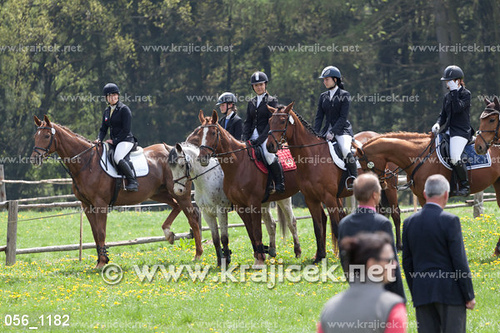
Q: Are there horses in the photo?
A: Yes, there is a horse.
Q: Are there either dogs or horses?
A: Yes, there is a horse.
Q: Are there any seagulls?
A: No, there are no seagulls.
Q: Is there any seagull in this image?
A: No, there are no seagulls.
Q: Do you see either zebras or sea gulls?
A: No, there are no sea gulls or zebras.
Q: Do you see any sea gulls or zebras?
A: No, there are no sea gulls or zebras.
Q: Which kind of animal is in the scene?
A: The animal is a horse.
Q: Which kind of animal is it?
A: The animal is a horse.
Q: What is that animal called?
A: This is a horse.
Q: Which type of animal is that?
A: This is a horse.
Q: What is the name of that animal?
A: This is a horse.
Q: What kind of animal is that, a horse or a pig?
A: This is a horse.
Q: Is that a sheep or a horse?
A: That is a horse.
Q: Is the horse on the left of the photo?
A: Yes, the horse is on the left of the image.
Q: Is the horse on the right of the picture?
A: No, the horse is on the left of the image.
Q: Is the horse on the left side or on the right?
A: The horse is on the left of the image.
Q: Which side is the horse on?
A: The horse is on the left of the image.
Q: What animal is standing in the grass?
A: The animal is a horse.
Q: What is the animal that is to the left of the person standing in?
A: The horse is standing in the grass.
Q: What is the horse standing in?
A: The horse is standing in the grass.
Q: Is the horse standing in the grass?
A: Yes, the horse is standing in the grass.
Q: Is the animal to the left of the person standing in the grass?
A: Yes, the horse is standing in the grass.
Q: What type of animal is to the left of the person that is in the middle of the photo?
A: The animal is a horse.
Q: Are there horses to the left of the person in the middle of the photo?
A: Yes, there is a horse to the left of the person.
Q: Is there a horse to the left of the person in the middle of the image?
A: Yes, there is a horse to the left of the person.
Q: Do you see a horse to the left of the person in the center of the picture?
A: Yes, there is a horse to the left of the person.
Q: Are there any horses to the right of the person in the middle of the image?
A: No, the horse is to the left of the person.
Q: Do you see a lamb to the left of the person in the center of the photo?
A: No, there is a horse to the left of the person.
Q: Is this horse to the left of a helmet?
A: No, the horse is to the left of a person.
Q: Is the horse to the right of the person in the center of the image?
A: No, the horse is to the left of the person.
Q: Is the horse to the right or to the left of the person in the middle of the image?
A: The horse is to the left of the person.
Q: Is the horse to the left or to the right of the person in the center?
A: The horse is to the left of the person.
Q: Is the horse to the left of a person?
A: Yes, the horse is to the left of a person.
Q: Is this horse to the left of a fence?
A: No, the horse is to the left of a person.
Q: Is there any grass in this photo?
A: Yes, there is grass.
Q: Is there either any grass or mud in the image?
A: Yes, there is grass.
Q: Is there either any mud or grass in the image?
A: Yes, there is grass.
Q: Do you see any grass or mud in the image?
A: Yes, there is grass.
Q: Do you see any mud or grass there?
A: Yes, there is grass.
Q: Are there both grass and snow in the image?
A: No, there is grass but no snow.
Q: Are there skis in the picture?
A: No, there are no skis.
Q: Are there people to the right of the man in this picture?
A: Yes, there are people to the right of the man.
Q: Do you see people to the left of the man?
A: No, the people are to the right of the man.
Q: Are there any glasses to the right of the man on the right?
A: No, there are people to the right of the man.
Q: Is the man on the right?
A: Yes, the man is on the right of the image.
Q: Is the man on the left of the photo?
A: No, the man is on the right of the image.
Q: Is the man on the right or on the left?
A: The man is on the right of the image.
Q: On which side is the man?
A: The man is on the right of the image.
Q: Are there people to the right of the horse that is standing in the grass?
A: Yes, there is a person to the right of the horse.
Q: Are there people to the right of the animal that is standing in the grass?
A: Yes, there is a person to the right of the horse.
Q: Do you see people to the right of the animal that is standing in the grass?
A: Yes, there is a person to the right of the horse.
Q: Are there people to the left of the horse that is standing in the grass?
A: No, the person is to the right of the horse.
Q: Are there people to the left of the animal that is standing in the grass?
A: No, the person is to the right of the horse.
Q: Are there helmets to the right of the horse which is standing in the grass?
A: No, there is a person to the right of the horse.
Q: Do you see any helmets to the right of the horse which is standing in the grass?
A: No, there is a person to the right of the horse.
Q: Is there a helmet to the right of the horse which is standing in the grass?
A: No, there is a person to the right of the horse.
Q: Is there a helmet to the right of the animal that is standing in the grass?
A: No, there is a person to the right of the horse.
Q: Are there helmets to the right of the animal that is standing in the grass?
A: No, there is a person to the right of the horse.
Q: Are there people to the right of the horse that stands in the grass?
A: Yes, there is a person to the right of the horse.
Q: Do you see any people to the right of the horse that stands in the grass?
A: Yes, there is a person to the right of the horse.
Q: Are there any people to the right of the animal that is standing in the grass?
A: Yes, there is a person to the right of the horse.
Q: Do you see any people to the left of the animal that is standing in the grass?
A: No, the person is to the right of the horse.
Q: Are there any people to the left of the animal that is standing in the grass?
A: No, the person is to the right of the horse.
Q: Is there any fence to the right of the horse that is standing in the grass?
A: No, there is a person to the right of the horse.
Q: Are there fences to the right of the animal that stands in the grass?
A: No, there is a person to the right of the horse.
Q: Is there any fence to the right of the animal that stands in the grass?
A: No, there is a person to the right of the horse.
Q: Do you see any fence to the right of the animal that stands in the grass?
A: No, there is a person to the right of the horse.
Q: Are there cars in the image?
A: No, there are no cars.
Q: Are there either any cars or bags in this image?
A: No, there are no cars or bags.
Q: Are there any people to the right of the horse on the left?
A: Yes, there is a person to the right of the horse.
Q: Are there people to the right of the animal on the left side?
A: Yes, there is a person to the right of the horse.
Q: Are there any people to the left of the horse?
A: No, the person is to the right of the horse.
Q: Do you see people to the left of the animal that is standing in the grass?
A: No, the person is to the right of the horse.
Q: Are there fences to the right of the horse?
A: No, there is a person to the right of the horse.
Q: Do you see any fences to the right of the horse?
A: No, there is a person to the right of the horse.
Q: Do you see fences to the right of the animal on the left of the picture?
A: No, there is a person to the right of the horse.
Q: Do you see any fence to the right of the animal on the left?
A: No, there is a person to the right of the horse.